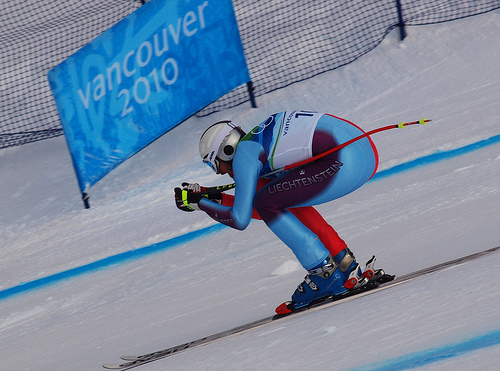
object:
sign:
[46, 0, 250, 195]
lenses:
[204, 160, 216, 172]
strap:
[223, 132, 232, 148]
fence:
[0, 0, 500, 145]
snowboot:
[101, 245, 500, 370]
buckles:
[310, 263, 339, 279]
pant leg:
[289, 209, 363, 280]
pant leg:
[259, 208, 330, 271]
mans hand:
[180, 179, 210, 196]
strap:
[182, 190, 189, 207]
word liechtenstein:
[268, 160, 344, 195]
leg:
[250, 173, 350, 312]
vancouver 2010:
[72, 1, 211, 123]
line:
[376, 134, 500, 178]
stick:
[183, 117, 434, 193]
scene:
[0, 0, 500, 371]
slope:
[340, 56, 453, 117]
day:
[0, 12, 500, 371]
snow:
[0, 0, 500, 371]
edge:
[290, 293, 297, 308]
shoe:
[274, 255, 367, 318]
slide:
[481, 250, 497, 259]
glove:
[173, 187, 203, 212]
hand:
[172, 187, 204, 212]